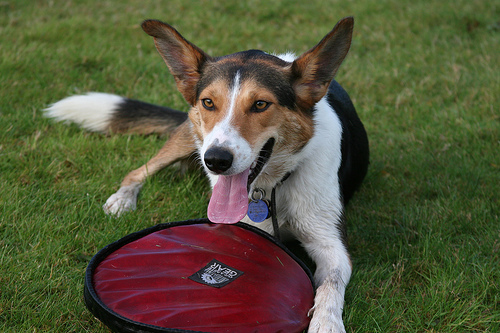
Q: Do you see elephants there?
A: No, there are no elephants.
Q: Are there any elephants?
A: No, there are no elephants.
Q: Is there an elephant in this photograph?
A: No, there are no elephants.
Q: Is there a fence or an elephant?
A: No, there are no elephants or fences.